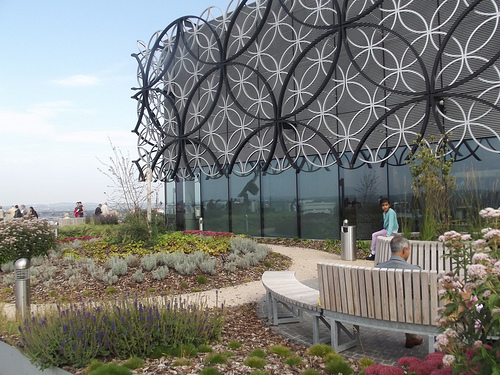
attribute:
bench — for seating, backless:
[372, 227, 492, 275]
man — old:
[370, 239, 430, 289]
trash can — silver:
[339, 224, 355, 263]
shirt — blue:
[381, 209, 399, 238]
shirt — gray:
[375, 260, 420, 271]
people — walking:
[10, 204, 43, 219]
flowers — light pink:
[2, 215, 56, 262]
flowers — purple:
[180, 227, 237, 240]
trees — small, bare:
[97, 135, 172, 221]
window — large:
[261, 162, 301, 236]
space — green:
[9, 272, 259, 333]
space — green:
[5, 328, 384, 358]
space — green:
[4, 219, 129, 245]